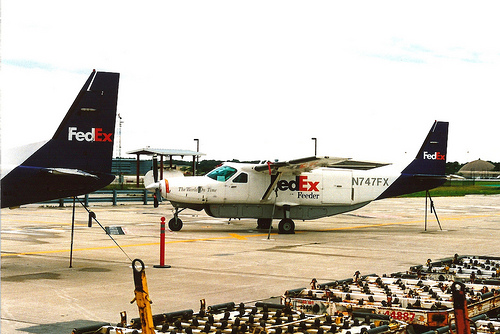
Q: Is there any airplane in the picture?
A: Yes, there is an airplane.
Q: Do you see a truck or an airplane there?
A: Yes, there is an airplane.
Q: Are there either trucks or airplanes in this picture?
A: Yes, there is an airplane.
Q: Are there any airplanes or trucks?
A: Yes, there is an airplane.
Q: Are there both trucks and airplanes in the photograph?
A: No, there is an airplane but no trucks.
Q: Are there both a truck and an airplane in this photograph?
A: No, there is an airplane but no trucks.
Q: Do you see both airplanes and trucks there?
A: No, there is an airplane but no trucks.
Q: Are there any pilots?
A: No, there are no pilots.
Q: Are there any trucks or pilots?
A: No, there are no pilots or trucks.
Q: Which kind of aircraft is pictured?
A: The aircraft is an airplane.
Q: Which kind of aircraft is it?
A: The aircraft is an airplane.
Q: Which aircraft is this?
A: This is an airplane.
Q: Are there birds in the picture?
A: No, there are no birds.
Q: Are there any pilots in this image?
A: No, there are no pilots.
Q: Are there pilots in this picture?
A: No, there are no pilots.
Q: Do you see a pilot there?
A: No, there are no pilots.